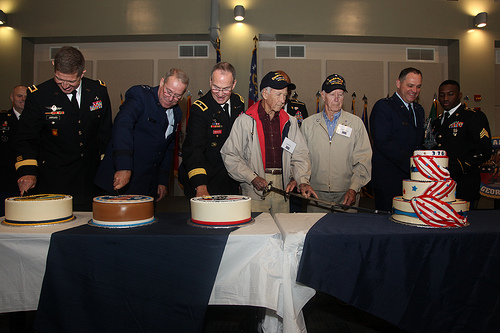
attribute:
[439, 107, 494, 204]
uniform — military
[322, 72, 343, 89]
uniform — military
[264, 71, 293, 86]
uniform — military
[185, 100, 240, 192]
uniform — military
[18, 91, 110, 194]
uniform — military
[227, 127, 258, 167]
jacket — beige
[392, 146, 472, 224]
cake — red, white, blue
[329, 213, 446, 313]
cover — blue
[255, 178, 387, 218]
sword — long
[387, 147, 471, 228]
cake — red, white, blue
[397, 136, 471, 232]
cake — fancy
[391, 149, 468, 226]
cake — red, blue, white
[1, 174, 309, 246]
cakes — 3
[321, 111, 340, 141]
shirt — blue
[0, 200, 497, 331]
table cloth — white, blue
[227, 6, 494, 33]
lights — small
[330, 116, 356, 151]
name tag — white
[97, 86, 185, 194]
jacket — blue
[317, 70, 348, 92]
cap — black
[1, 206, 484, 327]
table — blue, white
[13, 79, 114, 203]
uniform — black, yellow